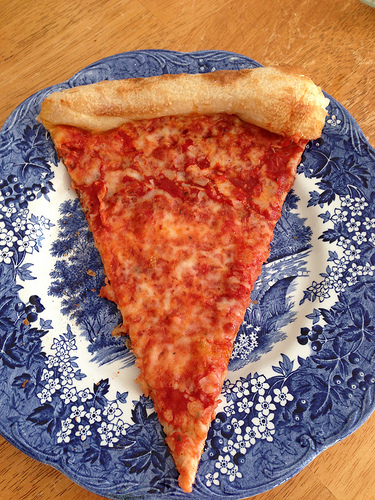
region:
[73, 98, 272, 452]
one slice of pizza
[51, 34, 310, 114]
crust is light brown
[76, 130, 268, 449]
orange sauce on pizza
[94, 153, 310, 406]
white cheese on pizza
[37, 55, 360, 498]
blue and white plate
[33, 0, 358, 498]
plate on wooden table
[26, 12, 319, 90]
table is light brown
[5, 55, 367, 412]
floral design on plate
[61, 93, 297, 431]
slice of cheese pizza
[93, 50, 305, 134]
dark brown spot on crust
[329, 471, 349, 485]
this is the table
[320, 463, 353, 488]
the table is wooden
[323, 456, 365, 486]
the table is brown in color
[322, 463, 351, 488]
the table is clean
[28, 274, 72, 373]
this is a plate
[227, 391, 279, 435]
drawings of some flowers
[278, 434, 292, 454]
the plate is blue in color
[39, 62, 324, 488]
this is a pizza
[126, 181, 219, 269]
the pizza is big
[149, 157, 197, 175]
the pizza is red in color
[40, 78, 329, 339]
a slice of pizza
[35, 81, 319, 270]
this is a cheese pizza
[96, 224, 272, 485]
this pizza only has sauce and cheese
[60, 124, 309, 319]
the pizza is red and light brown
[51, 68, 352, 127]
the crust is golden brown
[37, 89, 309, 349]
this slice of pizza has been cooked really well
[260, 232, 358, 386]
a blue plate for the pizza slice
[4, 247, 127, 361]
pizza crumbs on the plate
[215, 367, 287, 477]
white flower design on the bue plate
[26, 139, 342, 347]
this plate has unique decorations on it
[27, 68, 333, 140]
thick crust on the end of the slice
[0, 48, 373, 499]
pizza on a plate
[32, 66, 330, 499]
triangle slice of pizza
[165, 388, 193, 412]
sauce sticking out from under the cheese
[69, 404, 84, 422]
drawing of a white flower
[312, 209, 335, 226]
blue leaves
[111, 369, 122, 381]
stain on the plate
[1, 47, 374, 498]
Cheese pizza sitting on plate.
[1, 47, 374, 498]
Pizza on a blue and white plate.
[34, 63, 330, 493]
Cheese pizza is yellow, red and orange.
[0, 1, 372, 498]
Plate is on wood table.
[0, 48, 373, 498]
Blue plate has white flower design.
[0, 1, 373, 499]
Pizza on blue plate on table.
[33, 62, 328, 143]
Pizza crust is light brown.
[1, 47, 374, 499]
Pizza is lying on blue plate with designs.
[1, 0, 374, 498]
Table is made of wood.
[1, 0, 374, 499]
Plate of pizza on table.